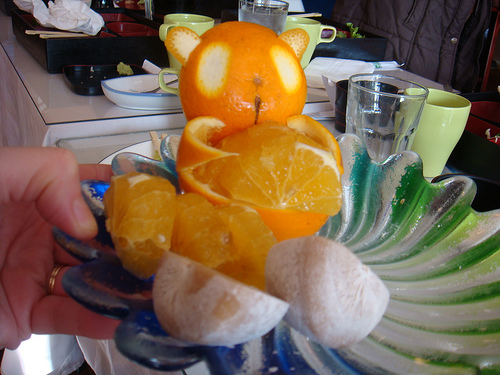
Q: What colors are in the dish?
A: Blue and green.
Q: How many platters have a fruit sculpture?
A: 1.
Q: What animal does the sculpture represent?
A: Panda bear.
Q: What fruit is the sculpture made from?
A: Oranges.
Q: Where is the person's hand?
A: On the left.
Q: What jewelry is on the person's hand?
A: Ring.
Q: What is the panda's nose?
A: The stem.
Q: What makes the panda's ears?
A: Pieces of peel.